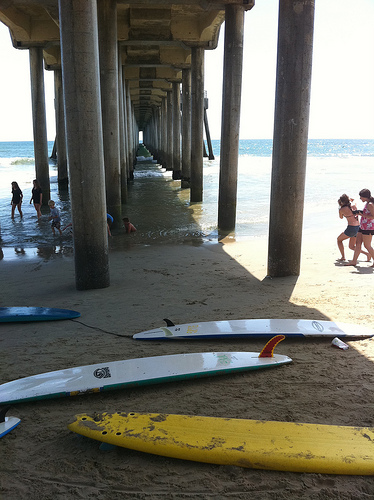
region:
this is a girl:
[333, 191, 365, 263]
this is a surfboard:
[68, 379, 365, 485]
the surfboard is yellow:
[76, 388, 373, 497]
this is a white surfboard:
[15, 317, 308, 414]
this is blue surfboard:
[8, 290, 97, 358]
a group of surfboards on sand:
[17, 281, 345, 496]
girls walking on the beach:
[327, 175, 371, 268]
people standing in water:
[8, 164, 72, 245]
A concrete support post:
[59, 2, 111, 289]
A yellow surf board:
[69, 410, 373, 476]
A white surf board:
[2, 333, 292, 406]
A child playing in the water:
[43, 198, 63, 238]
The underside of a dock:
[0, 0, 315, 290]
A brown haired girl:
[347, 188, 373, 265]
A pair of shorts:
[345, 224, 359, 236]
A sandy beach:
[2, 244, 373, 498]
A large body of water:
[0, 138, 373, 261]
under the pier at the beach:
[6, 7, 362, 320]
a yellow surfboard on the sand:
[67, 404, 372, 479]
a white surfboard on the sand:
[0, 333, 301, 407]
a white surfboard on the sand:
[125, 302, 372, 347]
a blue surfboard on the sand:
[0, 294, 86, 330]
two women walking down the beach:
[330, 178, 373, 274]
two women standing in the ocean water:
[8, 175, 44, 227]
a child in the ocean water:
[45, 197, 66, 238]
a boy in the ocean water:
[119, 214, 146, 236]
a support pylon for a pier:
[251, 0, 320, 284]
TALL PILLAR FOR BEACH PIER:
[271, 42, 307, 275]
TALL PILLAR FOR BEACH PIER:
[61, 47, 119, 290]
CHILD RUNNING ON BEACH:
[331, 190, 360, 270]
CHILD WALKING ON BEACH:
[349, 186, 373, 270]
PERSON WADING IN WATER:
[8, 179, 25, 226]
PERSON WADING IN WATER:
[30, 176, 41, 219]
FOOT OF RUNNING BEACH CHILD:
[334, 251, 346, 265]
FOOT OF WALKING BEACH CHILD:
[348, 256, 359, 267]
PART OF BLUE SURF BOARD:
[5, 304, 89, 322]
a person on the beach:
[331, 193, 372, 264]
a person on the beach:
[345, 187, 372, 265]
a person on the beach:
[44, 201, 64, 240]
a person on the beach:
[121, 214, 135, 234]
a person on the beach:
[7, 181, 24, 220]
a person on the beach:
[28, 178, 44, 220]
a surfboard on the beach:
[132, 317, 372, 347]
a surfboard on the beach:
[0, 304, 83, 322]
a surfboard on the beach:
[0, 332, 291, 405]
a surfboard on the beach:
[65, 407, 372, 473]